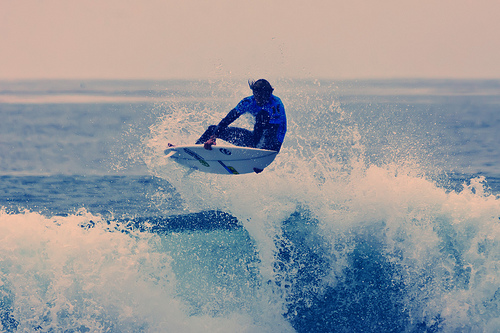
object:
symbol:
[220, 148, 231, 155]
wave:
[253, 183, 498, 309]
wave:
[13, 189, 242, 326]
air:
[0, 0, 499, 221]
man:
[167, 79, 286, 156]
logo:
[272, 104, 281, 117]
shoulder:
[269, 95, 285, 125]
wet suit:
[211, 96, 287, 147]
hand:
[203, 140, 216, 151]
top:
[235, 96, 288, 143]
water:
[0, 191, 300, 330]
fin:
[164, 150, 177, 157]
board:
[159, 145, 278, 176]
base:
[165, 146, 274, 175]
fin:
[184, 148, 211, 167]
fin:
[253, 167, 264, 173]